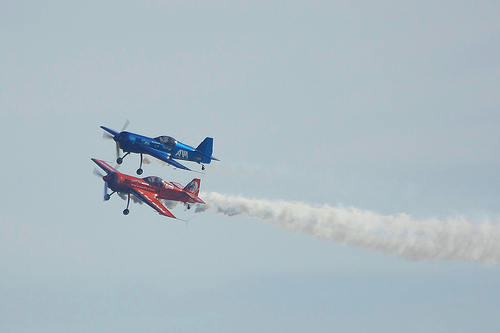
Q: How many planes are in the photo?
A: Two.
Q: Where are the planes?
A: In the sky.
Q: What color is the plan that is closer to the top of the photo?
A: Blue.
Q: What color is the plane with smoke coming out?
A: Red.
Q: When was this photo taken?
A: Daytime.